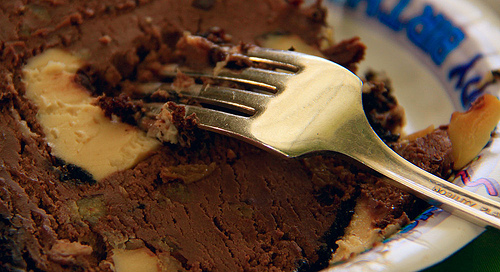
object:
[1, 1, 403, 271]
ice cream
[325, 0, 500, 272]
bowl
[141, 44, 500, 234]
fork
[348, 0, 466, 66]
writing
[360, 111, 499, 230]
handle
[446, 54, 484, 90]
y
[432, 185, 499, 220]
writing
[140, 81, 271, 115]
tine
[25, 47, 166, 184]
vanilla